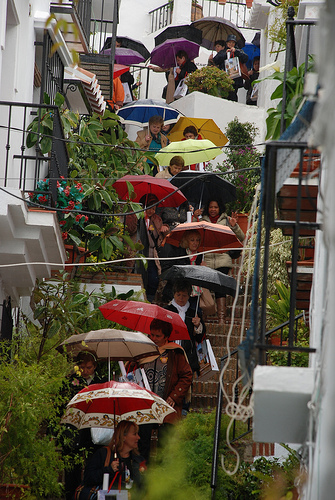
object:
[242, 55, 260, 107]
person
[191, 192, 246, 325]
person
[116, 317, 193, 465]
person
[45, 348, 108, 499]
person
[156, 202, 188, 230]
person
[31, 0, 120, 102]
balcony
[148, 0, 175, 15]
railing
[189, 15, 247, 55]
umbrellas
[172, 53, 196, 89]
woman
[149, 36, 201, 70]
umbrella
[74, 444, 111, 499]
purse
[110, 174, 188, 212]
umbrella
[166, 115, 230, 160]
umbrella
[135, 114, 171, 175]
woman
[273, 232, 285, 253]
flower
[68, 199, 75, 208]
flower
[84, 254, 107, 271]
flower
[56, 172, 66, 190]
flower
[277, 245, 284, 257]
flower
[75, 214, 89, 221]
blossom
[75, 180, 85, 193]
blossom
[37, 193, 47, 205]
blossom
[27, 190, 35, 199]
blossom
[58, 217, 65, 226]
blossom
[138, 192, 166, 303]
people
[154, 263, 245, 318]
umbrellas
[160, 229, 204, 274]
lady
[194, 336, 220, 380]
shopping bag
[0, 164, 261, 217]
cable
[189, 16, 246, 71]
holding umbrellas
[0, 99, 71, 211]
balcony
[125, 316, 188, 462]
woman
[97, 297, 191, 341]
umbrella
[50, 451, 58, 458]
leaf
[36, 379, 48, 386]
leaf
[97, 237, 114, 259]
leaf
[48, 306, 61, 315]
leaf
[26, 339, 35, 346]
leaf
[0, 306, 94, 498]
tree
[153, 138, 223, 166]
umbrella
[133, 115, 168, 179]
blonde woman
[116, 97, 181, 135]
umbrella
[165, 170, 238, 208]
umbrella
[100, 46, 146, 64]
umbrella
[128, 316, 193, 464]
woman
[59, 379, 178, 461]
umbrella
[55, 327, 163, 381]
umbrellas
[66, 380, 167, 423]
umbrellas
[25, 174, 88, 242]
flowers stairs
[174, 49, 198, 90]
man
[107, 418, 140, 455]
hair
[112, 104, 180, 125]
trim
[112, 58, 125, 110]
man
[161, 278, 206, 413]
woman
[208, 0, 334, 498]
building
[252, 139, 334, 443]
balcony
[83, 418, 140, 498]
people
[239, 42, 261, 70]
umbrellas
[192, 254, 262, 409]
stairs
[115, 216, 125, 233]
flowers